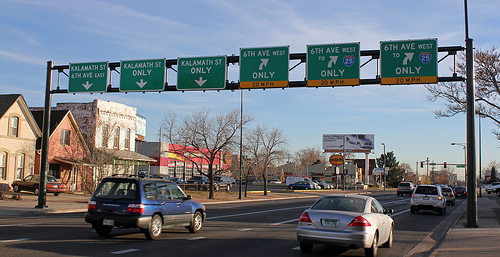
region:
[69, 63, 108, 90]
sign is green and white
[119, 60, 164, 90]
sign background is green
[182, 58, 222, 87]
the text is white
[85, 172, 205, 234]
suv driving on road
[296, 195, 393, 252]
car driving on street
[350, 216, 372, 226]
rear light is red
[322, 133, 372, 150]
billboard with a car on it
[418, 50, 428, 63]
red white and blue symbol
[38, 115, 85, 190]
house is painted red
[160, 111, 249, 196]
no leaves on tree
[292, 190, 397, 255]
light gray car driving on street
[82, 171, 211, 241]
blue and gray car driving on street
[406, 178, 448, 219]
white car driving on street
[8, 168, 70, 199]
car parked in driveway near street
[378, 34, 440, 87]
rectangular green white and yellow traffic sign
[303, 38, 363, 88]
rectangular green white and yellow traffic sign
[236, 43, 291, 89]
rectangular green white and yellow traffic sign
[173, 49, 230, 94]
green and white traffic sign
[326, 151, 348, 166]
oval yellow sign near street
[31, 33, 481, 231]
metal poles holding up many rectangular signs over road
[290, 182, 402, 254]
this is a car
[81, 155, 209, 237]
this is a car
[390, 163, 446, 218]
this is a car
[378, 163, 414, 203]
this is a car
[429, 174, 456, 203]
this is a car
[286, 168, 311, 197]
this is a car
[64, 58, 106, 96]
this is a sign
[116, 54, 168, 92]
this is a sign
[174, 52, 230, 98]
this is a sign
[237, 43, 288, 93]
this is a sign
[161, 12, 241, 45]
this is the sky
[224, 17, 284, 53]
the sky bis blue in color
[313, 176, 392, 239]
this is a car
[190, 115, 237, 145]
this is a tree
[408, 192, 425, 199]
the car is white in color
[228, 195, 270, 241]
this is the road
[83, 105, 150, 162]
this is a building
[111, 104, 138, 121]
this is the wall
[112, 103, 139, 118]
the wall is white in color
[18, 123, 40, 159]
the wall is brown in color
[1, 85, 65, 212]
A red car is parked in the driveway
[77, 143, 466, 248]
Several vehicles are driving down the road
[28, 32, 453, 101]
The sign denotes street directions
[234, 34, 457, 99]
The right lanes are for 6th ave west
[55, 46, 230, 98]
The left lanes are for Kalamath st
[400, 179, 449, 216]
This vehicle's brake lights are on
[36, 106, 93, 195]
The front of a peach colored house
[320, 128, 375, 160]
There is a billboard with a car on it in the background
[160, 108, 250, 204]
The tree doesn't have any leaves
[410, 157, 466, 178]
The traffic light is red